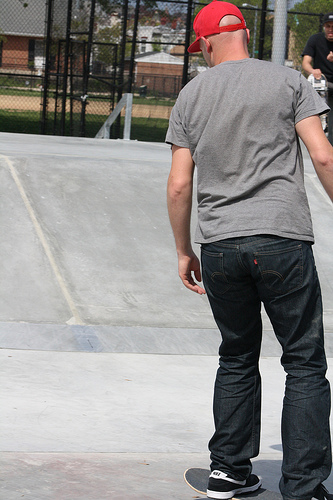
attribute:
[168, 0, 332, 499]
man — skateboarding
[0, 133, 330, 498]
concrete — sloped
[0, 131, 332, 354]
wall — concrete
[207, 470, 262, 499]
sneaker — black, white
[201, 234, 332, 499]
pants — blue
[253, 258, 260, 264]
tag — red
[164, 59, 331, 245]
shirt — gray, short sleeved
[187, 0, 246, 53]
hat — red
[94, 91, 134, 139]
railing — metal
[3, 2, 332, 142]
fence — black, mesh, chain link, metal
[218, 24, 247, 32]
fastener — red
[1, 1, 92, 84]
house — brick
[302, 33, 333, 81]
shirt — black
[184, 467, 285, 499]
skateboard — gray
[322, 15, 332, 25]
hat — black